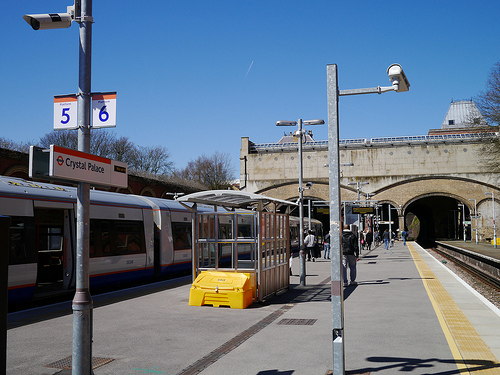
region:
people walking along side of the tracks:
[296, 212, 416, 285]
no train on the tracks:
[422, 219, 497, 304]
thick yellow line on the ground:
[394, 241, 488, 373]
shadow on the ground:
[352, 348, 499, 374]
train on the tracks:
[4, 158, 332, 315]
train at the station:
[2, 151, 494, 373]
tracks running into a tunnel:
[404, 191, 467, 270]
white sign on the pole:
[44, 145, 146, 191]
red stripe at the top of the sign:
[52, 142, 119, 165]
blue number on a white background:
[96, 102, 113, 122]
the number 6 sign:
[91, 90, 120, 135]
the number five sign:
[53, 99, 78, 127]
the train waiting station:
[195, 190, 292, 303]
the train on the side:
[3, 173, 318, 305]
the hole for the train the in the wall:
[401, 196, 471, 248]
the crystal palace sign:
[53, 151, 143, 193]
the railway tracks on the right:
[435, 231, 497, 321]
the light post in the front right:
[325, 61, 420, 373]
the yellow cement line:
[405, 237, 499, 372]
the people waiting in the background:
[303, 222, 405, 300]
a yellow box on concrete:
[178, 265, 260, 312]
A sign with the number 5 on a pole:
[43, 81, 84, 135]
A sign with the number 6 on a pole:
[85, 86, 124, 133]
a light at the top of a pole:
[314, 55, 419, 116]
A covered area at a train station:
[165, 179, 300, 315]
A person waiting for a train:
[301, 229, 318, 262]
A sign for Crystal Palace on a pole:
[23, 140, 138, 199]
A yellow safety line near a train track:
[403, 259, 460, 333]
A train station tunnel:
[392, 180, 474, 261]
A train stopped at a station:
[8, 183, 184, 298]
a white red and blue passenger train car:
[3, 175, 157, 308]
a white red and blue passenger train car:
[131, 193, 258, 277]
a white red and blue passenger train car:
[278, 211, 323, 250]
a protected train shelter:
[166, 187, 296, 308]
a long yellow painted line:
[402, 239, 498, 374]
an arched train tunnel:
[402, 189, 472, 245]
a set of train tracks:
[417, 240, 498, 297]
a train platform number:
[88, 89, 114, 129]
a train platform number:
[53, 92, 77, 127]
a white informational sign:
[45, 147, 127, 193]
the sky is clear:
[131, 9, 183, 69]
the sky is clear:
[211, 25, 346, 103]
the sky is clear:
[335, 3, 442, 73]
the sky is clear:
[158, 75, 226, 131]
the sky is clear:
[153, 42, 189, 83]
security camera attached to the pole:
[310, 10, 437, 132]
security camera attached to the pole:
[22, 0, 106, 52]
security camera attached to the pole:
[278, 36, 424, 110]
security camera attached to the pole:
[274, 118, 321, 155]